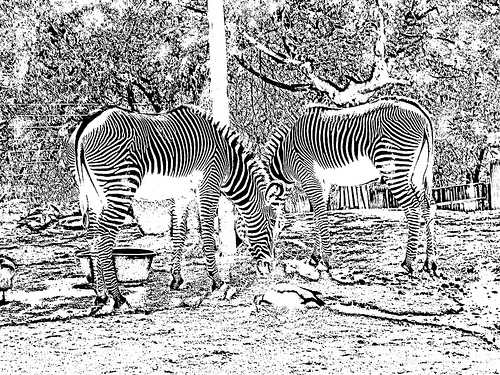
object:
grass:
[0, 210, 499, 372]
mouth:
[246, 257, 273, 274]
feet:
[193, 170, 233, 299]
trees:
[0, 0, 208, 104]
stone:
[253, 281, 327, 311]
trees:
[226, 0, 500, 125]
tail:
[424, 135, 439, 196]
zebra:
[252, 92, 441, 275]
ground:
[310, 288, 451, 326]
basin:
[73, 244, 158, 288]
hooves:
[110, 298, 137, 315]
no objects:
[1, 307, 499, 374]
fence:
[429, 181, 489, 210]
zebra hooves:
[399, 244, 424, 275]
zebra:
[236, 94, 439, 277]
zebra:
[60, 89, 290, 314]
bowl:
[78, 247, 153, 285]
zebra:
[65, 97, 282, 310]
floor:
[76, 310, 161, 346]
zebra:
[228, 95, 437, 282]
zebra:
[64, 103, 277, 311]